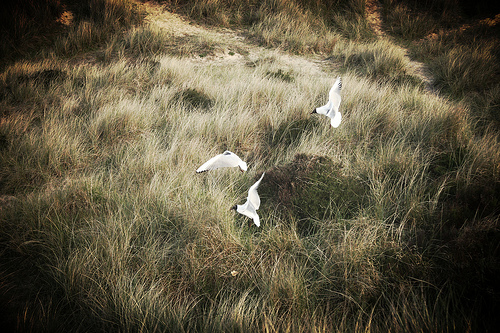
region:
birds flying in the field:
[190, 79, 333, 244]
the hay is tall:
[192, 83, 251, 121]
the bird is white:
[243, 199, 263, 223]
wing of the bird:
[334, 118, 339, 131]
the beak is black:
[230, 200, 235, 213]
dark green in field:
[268, 62, 291, 85]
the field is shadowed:
[414, 15, 474, 100]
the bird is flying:
[313, 74, 355, 129]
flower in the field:
[45, 4, 91, 41]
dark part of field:
[413, 194, 466, 308]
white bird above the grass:
[192, 139, 253, 186]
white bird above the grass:
[225, 166, 272, 236]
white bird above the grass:
[302, 74, 347, 131]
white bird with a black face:
[302, 72, 349, 128]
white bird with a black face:
[225, 167, 272, 227]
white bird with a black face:
[189, 146, 249, 180]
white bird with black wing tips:
[191, 142, 249, 179]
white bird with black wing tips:
[224, 166, 268, 232]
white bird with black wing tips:
[305, 72, 350, 129]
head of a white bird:
[309, 104, 317, 117]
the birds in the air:
[193, 63, 353, 239]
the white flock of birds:
[190, 60, 347, 236]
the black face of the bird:
[227, 202, 239, 214]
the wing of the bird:
[241, 172, 268, 208]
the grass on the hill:
[270, 158, 383, 230]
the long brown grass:
[0, 5, 292, 130]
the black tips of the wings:
[194, 168, 211, 177]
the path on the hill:
[360, 0, 446, 115]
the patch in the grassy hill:
[155, 9, 325, 82]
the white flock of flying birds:
[168, 45, 360, 254]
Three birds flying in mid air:
[189, 74, 352, 227]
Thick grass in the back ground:
[4, 1, 499, 331]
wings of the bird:
[328, 76, 344, 109]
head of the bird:
[227, 202, 239, 212]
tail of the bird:
[236, 159, 248, 172]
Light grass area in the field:
[107, 55, 382, 240]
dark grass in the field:
[5, 0, 160, 56]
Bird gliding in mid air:
[307, 75, 342, 130]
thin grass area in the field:
[150, 15, 275, 60]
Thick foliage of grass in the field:
[1, 199, 498, 328]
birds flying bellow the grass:
[216, 95, 346, 222]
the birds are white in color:
[191, 147, 291, 236]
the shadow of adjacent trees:
[22, 202, 132, 305]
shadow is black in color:
[331, 263, 450, 330]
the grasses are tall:
[94, 185, 190, 269]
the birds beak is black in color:
[303, 102, 320, 126]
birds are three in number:
[193, 88, 358, 245]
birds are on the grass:
[200, 141, 300, 256]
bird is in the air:
[301, 89, 369, 131]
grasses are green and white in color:
[330, 182, 398, 252]